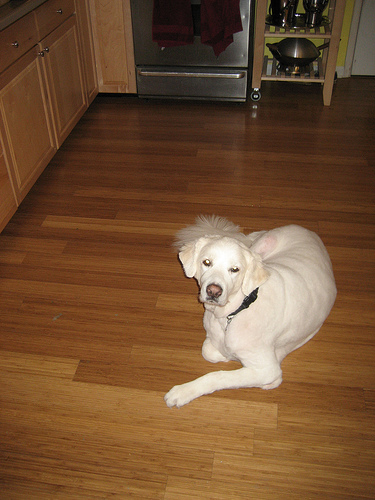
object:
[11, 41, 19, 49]
knobs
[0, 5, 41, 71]
drawers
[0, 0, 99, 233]
cabinets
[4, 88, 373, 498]
floor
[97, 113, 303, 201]
boards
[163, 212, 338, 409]
dog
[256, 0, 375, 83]
wall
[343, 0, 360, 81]
trim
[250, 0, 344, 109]
rack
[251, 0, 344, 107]
shelves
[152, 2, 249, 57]
towel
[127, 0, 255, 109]
oven door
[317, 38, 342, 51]
handle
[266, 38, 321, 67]
wok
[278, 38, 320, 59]
lid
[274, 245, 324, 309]
fur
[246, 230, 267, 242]
tail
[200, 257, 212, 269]
eyes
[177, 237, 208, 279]
ears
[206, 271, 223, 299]
nose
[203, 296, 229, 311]
mouth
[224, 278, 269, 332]
collar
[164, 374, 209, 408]
paw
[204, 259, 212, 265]
camera flash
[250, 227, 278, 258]
leg